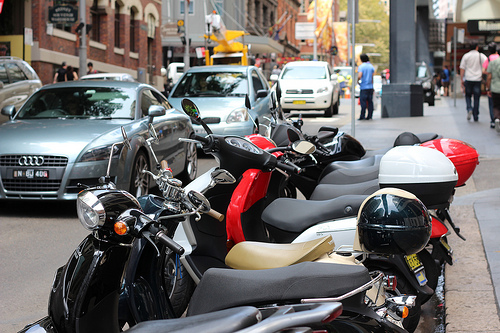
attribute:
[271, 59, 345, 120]
car — white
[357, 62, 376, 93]
shirt — blue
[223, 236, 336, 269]
seat — gold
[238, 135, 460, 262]
scooter — red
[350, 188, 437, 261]
motorcycle helmet — black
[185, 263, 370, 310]
seat — black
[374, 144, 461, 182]
case lid — white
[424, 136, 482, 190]
case — red